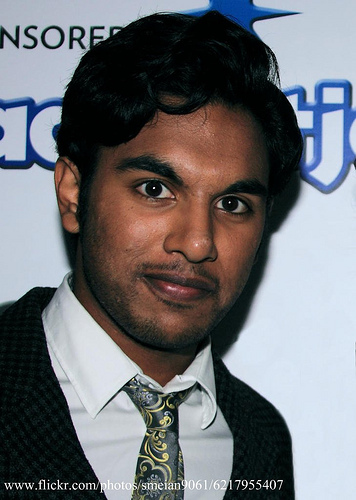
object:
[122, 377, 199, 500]
tie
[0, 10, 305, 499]
man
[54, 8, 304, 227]
hair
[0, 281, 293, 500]
suit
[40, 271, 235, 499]
shirt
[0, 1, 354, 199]
advertisement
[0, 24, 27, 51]
letters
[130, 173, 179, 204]
eye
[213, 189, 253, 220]
eye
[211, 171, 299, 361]
shadow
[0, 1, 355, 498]
billboard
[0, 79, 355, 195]
word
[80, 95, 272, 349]
face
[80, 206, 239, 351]
whiskers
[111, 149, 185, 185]
eyebrow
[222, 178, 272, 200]
eyebrow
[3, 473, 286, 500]
website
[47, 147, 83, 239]
ear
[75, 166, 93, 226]
sideburn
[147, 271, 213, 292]
lip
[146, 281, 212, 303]
lip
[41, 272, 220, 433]
collar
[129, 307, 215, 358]
chin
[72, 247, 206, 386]
neck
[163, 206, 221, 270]
nose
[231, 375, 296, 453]
shoulder